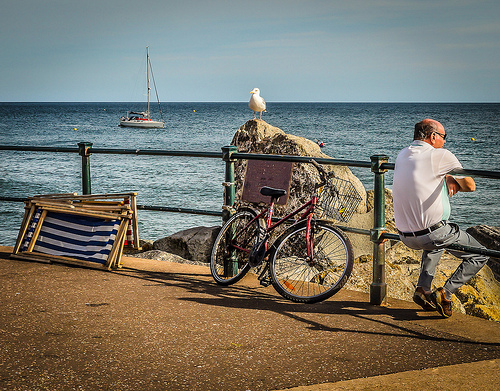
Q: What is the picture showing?
A: It is showing an ocean.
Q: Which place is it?
A: It is an ocean.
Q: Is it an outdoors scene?
A: Yes, it is outdoors.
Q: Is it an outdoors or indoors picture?
A: It is outdoors.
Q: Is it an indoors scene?
A: No, it is outdoors.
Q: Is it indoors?
A: No, it is outdoors.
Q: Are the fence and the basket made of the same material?
A: Yes, both the fence and the basket are made of metal.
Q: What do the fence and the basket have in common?
A: The material, both the fence and the basket are metallic.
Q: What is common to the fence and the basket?
A: The material, both the fence and the basket are metallic.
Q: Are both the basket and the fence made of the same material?
A: Yes, both the basket and the fence are made of metal.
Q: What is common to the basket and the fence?
A: The material, both the basket and the fence are metallic.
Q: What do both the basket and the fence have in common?
A: The material, both the basket and the fence are metallic.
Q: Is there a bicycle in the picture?
A: Yes, there is a bicycle.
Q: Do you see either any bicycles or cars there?
A: Yes, there is a bicycle.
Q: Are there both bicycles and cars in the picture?
A: No, there is a bicycle but no cars.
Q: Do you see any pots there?
A: No, there are no pots.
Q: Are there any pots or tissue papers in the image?
A: No, there are no pots or tissue papers.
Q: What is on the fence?
A: The bicycle is on the fence.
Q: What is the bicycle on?
A: The bicycle is on the fence.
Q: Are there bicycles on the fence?
A: Yes, there is a bicycle on the fence.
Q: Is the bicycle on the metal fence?
A: Yes, the bicycle is on the fence.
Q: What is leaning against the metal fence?
A: The bicycle is leaning against the fence.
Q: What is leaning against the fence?
A: The bicycle is leaning against the fence.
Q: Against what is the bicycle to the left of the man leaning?
A: The bicycle is leaning against the fence.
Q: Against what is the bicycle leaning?
A: The bicycle is leaning against the fence.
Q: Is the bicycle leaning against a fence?
A: Yes, the bicycle is leaning against a fence.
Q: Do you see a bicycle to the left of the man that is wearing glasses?
A: Yes, there is a bicycle to the left of the man.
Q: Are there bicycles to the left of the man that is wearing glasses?
A: Yes, there is a bicycle to the left of the man.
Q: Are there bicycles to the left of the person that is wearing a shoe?
A: Yes, there is a bicycle to the left of the man.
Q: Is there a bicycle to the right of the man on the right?
A: No, the bicycle is to the left of the man.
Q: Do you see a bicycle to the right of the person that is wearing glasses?
A: No, the bicycle is to the left of the man.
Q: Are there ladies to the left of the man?
A: No, there is a bicycle to the left of the man.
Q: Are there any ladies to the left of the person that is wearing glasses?
A: No, there is a bicycle to the left of the man.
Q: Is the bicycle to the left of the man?
A: Yes, the bicycle is to the left of the man.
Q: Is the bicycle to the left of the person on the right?
A: Yes, the bicycle is to the left of the man.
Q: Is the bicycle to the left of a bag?
A: No, the bicycle is to the left of the man.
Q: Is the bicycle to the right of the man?
A: No, the bicycle is to the left of the man.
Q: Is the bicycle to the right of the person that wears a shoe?
A: No, the bicycle is to the left of the man.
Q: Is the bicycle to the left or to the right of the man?
A: The bicycle is to the left of the man.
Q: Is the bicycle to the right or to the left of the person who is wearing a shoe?
A: The bicycle is to the left of the man.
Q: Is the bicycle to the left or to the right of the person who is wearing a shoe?
A: The bicycle is to the left of the man.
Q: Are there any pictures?
A: No, there are no pictures.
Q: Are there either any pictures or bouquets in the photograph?
A: No, there are no pictures or bouquets.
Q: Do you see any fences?
A: Yes, there is a fence.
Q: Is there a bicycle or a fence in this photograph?
A: Yes, there is a fence.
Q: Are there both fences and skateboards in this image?
A: No, there is a fence but no skateboards.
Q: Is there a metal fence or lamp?
A: Yes, there is a metal fence.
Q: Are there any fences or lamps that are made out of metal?
A: Yes, the fence is made of metal.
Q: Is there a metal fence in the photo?
A: Yes, there is a metal fence.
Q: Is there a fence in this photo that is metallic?
A: Yes, there is a fence that is metallic.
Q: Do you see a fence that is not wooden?
A: Yes, there is a metallic fence.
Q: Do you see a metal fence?
A: Yes, there is a fence that is made of metal.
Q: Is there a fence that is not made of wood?
A: Yes, there is a fence that is made of metal.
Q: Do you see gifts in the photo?
A: No, there are no gifts.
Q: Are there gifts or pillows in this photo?
A: No, there are no gifts or pillows.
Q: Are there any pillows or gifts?
A: No, there are no gifts or pillows.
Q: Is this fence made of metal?
A: Yes, the fence is made of metal.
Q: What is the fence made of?
A: The fence is made of metal.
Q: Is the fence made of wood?
A: No, the fence is made of metal.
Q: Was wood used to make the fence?
A: No, the fence is made of metal.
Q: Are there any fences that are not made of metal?
A: No, there is a fence but it is made of metal.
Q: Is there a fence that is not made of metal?
A: No, there is a fence but it is made of metal.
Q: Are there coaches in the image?
A: No, there are no coaches.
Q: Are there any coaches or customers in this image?
A: No, there are no coaches or customers.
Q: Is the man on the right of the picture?
A: Yes, the man is on the right of the image.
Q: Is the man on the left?
A: No, the man is on the right of the image.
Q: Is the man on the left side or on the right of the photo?
A: The man is on the right of the image.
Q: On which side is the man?
A: The man is on the right of the image.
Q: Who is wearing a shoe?
A: The man is wearing a shoe.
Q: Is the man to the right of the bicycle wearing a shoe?
A: Yes, the man is wearing a shoe.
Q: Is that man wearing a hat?
A: No, the man is wearing a shoe.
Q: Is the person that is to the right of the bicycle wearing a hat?
A: No, the man is wearing a shoe.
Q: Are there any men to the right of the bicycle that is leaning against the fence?
A: Yes, there is a man to the right of the bicycle.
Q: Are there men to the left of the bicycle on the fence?
A: No, the man is to the right of the bicycle.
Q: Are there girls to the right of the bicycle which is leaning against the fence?
A: No, there is a man to the right of the bicycle.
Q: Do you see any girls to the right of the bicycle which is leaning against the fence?
A: No, there is a man to the right of the bicycle.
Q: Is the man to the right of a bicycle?
A: Yes, the man is to the right of a bicycle.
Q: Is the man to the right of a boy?
A: No, the man is to the right of a bicycle.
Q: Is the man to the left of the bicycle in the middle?
A: No, the man is to the right of the bicycle.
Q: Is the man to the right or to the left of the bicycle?
A: The man is to the right of the bicycle.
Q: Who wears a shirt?
A: The man wears a shirt.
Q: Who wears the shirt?
A: The man wears a shirt.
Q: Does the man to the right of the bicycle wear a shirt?
A: Yes, the man wears a shirt.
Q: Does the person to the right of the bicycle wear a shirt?
A: Yes, the man wears a shirt.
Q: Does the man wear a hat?
A: No, the man wears a shirt.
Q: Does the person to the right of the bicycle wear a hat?
A: No, the man wears a shirt.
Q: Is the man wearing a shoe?
A: Yes, the man is wearing a shoe.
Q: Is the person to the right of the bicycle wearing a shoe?
A: Yes, the man is wearing a shoe.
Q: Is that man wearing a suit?
A: No, the man is wearing a shoe.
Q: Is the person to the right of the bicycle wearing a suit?
A: No, the man is wearing a shoe.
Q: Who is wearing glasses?
A: The man is wearing glasses.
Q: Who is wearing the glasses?
A: The man is wearing glasses.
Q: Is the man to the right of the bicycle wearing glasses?
A: Yes, the man is wearing glasses.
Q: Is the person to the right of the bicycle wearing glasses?
A: Yes, the man is wearing glasses.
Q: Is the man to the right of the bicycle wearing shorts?
A: No, the man is wearing glasses.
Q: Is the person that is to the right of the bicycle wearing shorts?
A: No, the man is wearing glasses.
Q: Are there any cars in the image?
A: No, there are no cars.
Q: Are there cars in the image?
A: No, there are no cars.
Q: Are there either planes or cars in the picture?
A: No, there are no cars or planes.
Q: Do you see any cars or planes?
A: No, there are no cars or planes.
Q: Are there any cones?
A: No, there are no cones.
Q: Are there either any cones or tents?
A: No, there are no cones or tents.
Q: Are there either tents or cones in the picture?
A: No, there are no cones or tents.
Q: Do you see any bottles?
A: No, there are no bottles.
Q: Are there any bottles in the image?
A: No, there are no bottles.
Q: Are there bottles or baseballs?
A: No, there are no bottles or baseballs.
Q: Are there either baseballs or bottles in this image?
A: No, there are no bottles or baseballs.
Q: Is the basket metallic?
A: Yes, the basket is metallic.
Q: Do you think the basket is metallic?
A: Yes, the basket is metallic.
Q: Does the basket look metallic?
A: Yes, the basket is metallic.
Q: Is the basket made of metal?
A: Yes, the basket is made of metal.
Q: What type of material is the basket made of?
A: The basket is made of metal.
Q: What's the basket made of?
A: The basket is made of metal.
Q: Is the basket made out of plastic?
A: No, the basket is made of metal.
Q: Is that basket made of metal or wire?
A: The basket is made of metal.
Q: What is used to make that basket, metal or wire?
A: The basket is made of metal.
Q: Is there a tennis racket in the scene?
A: No, there are no rackets.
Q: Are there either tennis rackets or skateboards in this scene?
A: No, there are no tennis rackets or skateboards.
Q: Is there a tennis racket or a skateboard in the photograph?
A: No, there are no rackets or skateboards.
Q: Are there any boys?
A: No, there are no boys.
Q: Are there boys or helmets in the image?
A: No, there are no boys or helmets.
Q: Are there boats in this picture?
A: Yes, there is a boat.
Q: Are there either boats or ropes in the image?
A: Yes, there is a boat.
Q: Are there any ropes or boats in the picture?
A: Yes, there is a boat.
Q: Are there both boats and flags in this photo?
A: No, there is a boat but no flags.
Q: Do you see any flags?
A: No, there are no flags.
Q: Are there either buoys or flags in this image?
A: No, there are no flags or buoys.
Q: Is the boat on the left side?
A: Yes, the boat is on the left of the image.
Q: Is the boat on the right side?
A: No, the boat is on the left of the image.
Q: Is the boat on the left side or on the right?
A: The boat is on the left of the image.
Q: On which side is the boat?
A: The boat is on the left of the image.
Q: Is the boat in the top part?
A: Yes, the boat is in the top of the image.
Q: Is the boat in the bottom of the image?
A: No, the boat is in the top of the image.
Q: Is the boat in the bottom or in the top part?
A: The boat is in the top of the image.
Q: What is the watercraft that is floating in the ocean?
A: The watercraft is a boat.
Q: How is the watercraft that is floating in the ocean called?
A: The watercraft is a boat.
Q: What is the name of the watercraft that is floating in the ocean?
A: The watercraft is a boat.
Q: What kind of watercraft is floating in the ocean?
A: The watercraft is a boat.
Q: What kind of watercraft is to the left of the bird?
A: The watercraft is a boat.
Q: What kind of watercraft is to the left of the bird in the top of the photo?
A: The watercraft is a boat.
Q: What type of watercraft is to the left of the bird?
A: The watercraft is a boat.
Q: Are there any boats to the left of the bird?
A: Yes, there is a boat to the left of the bird.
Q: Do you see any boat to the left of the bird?
A: Yes, there is a boat to the left of the bird.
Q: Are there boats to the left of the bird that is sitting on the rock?
A: Yes, there is a boat to the left of the bird.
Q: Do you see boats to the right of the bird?
A: No, the boat is to the left of the bird.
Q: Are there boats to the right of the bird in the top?
A: No, the boat is to the left of the bird.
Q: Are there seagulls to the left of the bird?
A: No, there is a boat to the left of the bird.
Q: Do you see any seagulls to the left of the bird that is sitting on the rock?
A: No, there is a boat to the left of the bird.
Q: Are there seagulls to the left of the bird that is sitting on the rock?
A: No, there is a boat to the left of the bird.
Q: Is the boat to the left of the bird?
A: Yes, the boat is to the left of the bird.